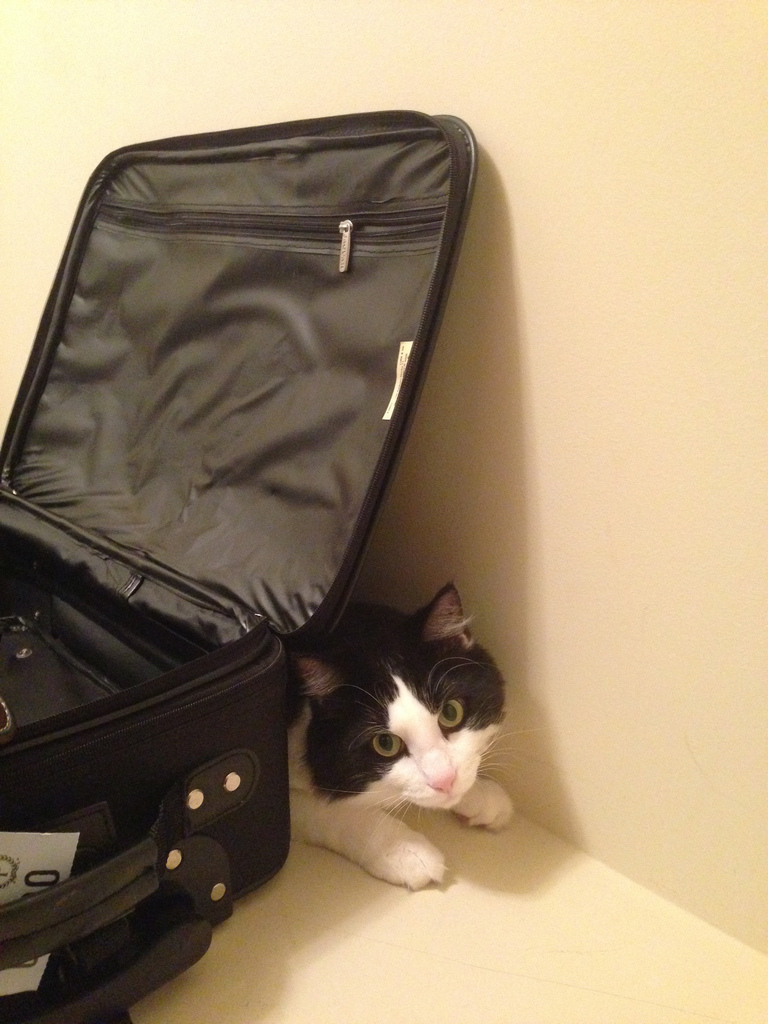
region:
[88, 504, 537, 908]
a cat behind a black suitcase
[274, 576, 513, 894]
a black and white cat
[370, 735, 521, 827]
a cat's nose with white whiskers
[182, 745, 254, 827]
metal rivets in black leather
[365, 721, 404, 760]
the eye of an animal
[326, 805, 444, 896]
the white paw of an animal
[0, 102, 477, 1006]
a suitcase that is opened up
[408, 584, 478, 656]
fur in an animal's ear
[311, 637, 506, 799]
the black and white face of a cat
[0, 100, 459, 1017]
A black open suitcase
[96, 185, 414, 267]
A zippered pocket on top of suitcase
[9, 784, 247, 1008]
Handles on the suitcase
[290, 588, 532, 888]
A black and white cat hiding behind suitcase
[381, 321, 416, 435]
A white tag on inside of suitcase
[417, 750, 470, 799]
Cats pink colored nose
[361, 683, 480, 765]
Cats green eyes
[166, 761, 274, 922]
Handle with silver trim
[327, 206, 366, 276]
Silver zipper tag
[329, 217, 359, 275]
Zipper on a luggage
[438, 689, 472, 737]
Eye of a cat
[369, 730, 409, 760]
Eye of a cat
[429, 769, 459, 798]
Nose of a cat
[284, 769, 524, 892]
two white paws of a cat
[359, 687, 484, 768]
two open eyes on a cat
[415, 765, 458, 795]
the pink nose of a cat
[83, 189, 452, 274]
a zipper inside of a suitcase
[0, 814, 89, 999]
a tage on the suitcase with a number 0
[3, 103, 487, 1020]
an open black suitcase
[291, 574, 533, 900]
a black-and-white cat behind a suitcase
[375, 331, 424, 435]
a small white tag sewn into the lid of a suitcase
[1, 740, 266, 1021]
handles on a suitcase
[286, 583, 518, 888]
black and white cat with green eyes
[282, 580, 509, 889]
black and white cat with long whiskers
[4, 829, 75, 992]
white tag hanging from suitcase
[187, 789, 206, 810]
silver metal button affixed to suitcase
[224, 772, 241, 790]
silver metal button affixed to suitcase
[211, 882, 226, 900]
silver metal button affixed to suitcase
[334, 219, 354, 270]
silver metal zipper inside the suitcase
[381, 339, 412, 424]
white tag inside of the suitcase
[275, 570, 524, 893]
the cat hides behind the suitcase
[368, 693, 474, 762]
the cat's eyes are wide open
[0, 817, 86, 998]
a tag attached to the suitcase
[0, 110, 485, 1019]
the suitcase is open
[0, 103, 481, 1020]
the suitcase is black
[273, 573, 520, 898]
the cat is black and white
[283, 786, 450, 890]
the cat's right front leg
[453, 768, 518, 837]
the cat's left front paw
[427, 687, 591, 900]
shadow cast by the cat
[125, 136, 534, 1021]
shadow cast by the suitcase